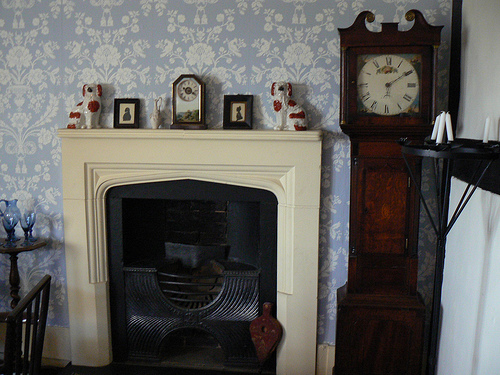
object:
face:
[356, 54, 419, 116]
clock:
[337, 8, 446, 375]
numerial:
[386, 57, 393, 66]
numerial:
[384, 105, 390, 114]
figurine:
[270, 82, 308, 131]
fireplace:
[57, 128, 322, 375]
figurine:
[66, 83, 103, 128]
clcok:
[170, 74, 207, 130]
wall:
[0, 0, 453, 131]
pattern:
[1, 0, 61, 110]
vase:
[0, 199, 22, 248]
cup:
[19, 212, 36, 246]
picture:
[119, 103, 136, 125]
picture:
[230, 102, 245, 122]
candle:
[430, 111, 454, 147]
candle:
[482, 117, 490, 143]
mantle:
[56, 128, 323, 375]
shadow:
[292, 81, 323, 129]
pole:
[398, 138, 500, 374]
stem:
[24, 232, 29, 241]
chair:
[3, 274, 51, 375]